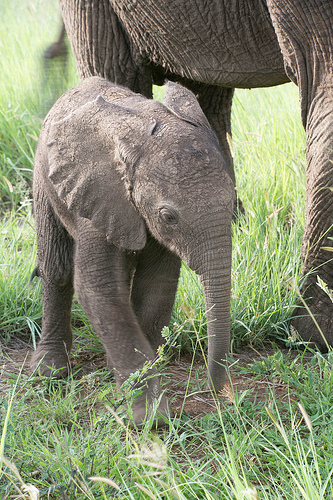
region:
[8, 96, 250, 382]
a young elephant standing in a field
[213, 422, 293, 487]
green grass of the field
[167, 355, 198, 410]
brown dirt of the ground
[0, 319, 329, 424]
a barren patch of land in the field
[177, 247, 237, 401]
trunk of the young elephant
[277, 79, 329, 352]
the leg of an adult elephant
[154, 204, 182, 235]
black eye of the young elephant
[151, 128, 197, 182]
grey skin of the elephant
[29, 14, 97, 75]
the tail of the adult elephant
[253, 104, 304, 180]
long green grass growing behind the elephants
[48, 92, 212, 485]
this is a elephant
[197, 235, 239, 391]
this is the trunk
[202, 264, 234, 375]
the trunk is long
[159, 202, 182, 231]
this is the eye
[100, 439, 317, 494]
this is a grass area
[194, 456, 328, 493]
the grass is green in color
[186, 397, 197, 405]
this is the soil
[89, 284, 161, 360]
this is the leg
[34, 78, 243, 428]
this is a small elephant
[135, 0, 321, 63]
this is the bigger elephant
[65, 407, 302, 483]
long green grass growing on the ground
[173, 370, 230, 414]
brown dirt of the ground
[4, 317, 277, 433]
sparse ground in the field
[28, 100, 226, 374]
a young elephant in a field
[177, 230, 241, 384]
the trunk of the young elephant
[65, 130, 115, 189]
grey skin of the young elephant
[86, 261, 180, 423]
front legs of the young elephant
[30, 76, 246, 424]
Gray baby elephant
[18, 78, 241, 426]
Baby elephant with long nose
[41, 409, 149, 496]
Green grass under elephant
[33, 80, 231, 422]
Baby elephant with four legs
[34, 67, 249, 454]
Baby elephant looking at camera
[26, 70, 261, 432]
Baby elephant near mother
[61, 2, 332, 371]
Baby elephant near mother elephant with four legs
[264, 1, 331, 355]
Large grey mother elephant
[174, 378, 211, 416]
Brown dirt under baby elephant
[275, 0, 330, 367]
Mother elephant near baby elephant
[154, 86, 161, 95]
A green patch of grass between elephants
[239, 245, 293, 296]
Grass beneath an elephant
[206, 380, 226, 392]
Tip of the trunk in the ground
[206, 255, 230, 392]
The trunk of a baby elephant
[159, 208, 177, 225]
The eye of a baby elephant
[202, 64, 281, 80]
The underside of an elephant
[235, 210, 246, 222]
The foot in the grass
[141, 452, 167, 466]
Whitish tuft of grass sticking out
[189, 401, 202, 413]
A patch without grass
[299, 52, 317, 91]
Elephant kin hanging loose